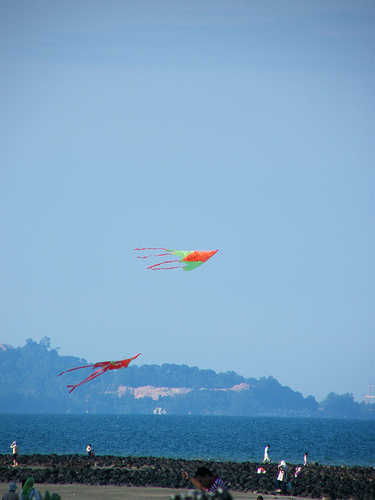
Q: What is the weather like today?
A: It is clear.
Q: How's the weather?
A: It is clear.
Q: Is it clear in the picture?
A: Yes, it is clear.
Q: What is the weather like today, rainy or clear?
A: It is clear.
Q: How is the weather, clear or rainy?
A: It is clear.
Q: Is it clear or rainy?
A: It is clear.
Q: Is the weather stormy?
A: No, it is clear.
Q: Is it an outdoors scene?
A: Yes, it is outdoors.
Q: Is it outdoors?
A: Yes, it is outdoors.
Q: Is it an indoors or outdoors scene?
A: It is outdoors.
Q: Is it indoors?
A: No, it is outdoors.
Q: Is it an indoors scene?
A: No, it is outdoors.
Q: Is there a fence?
A: No, there are no fences.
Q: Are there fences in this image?
A: No, there are no fences.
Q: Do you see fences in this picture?
A: No, there are no fences.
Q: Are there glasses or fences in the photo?
A: No, there are no fences or glasses.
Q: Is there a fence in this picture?
A: No, there are no fences.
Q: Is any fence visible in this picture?
A: No, there are no fences.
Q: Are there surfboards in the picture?
A: No, there are no surfboards.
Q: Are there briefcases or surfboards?
A: No, there are no surfboards or briefcases.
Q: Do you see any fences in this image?
A: No, there are no fences.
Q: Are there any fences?
A: No, there are no fences.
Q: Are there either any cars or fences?
A: No, there are no fences or cars.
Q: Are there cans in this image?
A: No, there are no cans.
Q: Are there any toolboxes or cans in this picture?
A: No, there are no cans or toolboxes.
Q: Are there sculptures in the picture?
A: No, there are no sculptures.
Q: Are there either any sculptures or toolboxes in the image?
A: No, there are no sculptures or toolboxes.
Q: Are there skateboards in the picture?
A: No, there are no skateboards.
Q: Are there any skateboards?
A: No, there are no skateboards.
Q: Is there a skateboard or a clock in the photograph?
A: No, there are no skateboards or clocks.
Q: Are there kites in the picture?
A: Yes, there is a kite.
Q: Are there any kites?
A: Yes, there is a kite.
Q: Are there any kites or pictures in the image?
A: Yes, there is a kite.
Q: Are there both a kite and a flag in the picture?
A: No, there is a kite but no flags.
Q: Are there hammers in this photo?
A: No, there are no hammers.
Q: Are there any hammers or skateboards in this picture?
A: No, there are no hammers or skateboards.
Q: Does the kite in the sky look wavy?
A: Yes, the kite is wavy.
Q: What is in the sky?
A: The kite is in the sky.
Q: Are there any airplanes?
A: No, there are no airplanes.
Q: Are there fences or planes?
A: No, there are no planes or fences.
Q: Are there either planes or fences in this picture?
A: No, there are no planes or fences.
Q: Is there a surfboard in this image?
A: No, there are no surfboards.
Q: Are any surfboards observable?
A: No, there are no surfboards.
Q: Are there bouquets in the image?
A: No, there are no bouquets.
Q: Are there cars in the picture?
A: No, there are no cars.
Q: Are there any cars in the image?
A: No, there are no cars.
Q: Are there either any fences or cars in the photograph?
A: No, there are no cars or fences.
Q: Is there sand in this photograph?
A: Yes, there is sand.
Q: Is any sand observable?
A: Yes, there is sand.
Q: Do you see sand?
A: Yes, there is sand.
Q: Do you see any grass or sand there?
A: Yes, there is sand.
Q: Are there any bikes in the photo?
A: No, there are no bikes.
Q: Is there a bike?
A: No, there are no bikes.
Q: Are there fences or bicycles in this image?
A: No, there are no bicycles or fences.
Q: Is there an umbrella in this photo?
A: No, there are no umbrellas.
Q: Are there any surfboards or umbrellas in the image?
A: No, there are no umbrellas or surfboards.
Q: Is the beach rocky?
A: Yes, the beach is rocky.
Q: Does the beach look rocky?
A: Yes, the beach is rocky.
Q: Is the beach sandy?
A: No, the beach is rocky.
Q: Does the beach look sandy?
A: No, the beach is rocky.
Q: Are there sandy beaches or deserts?
A: No, there is a beach but it is rocky.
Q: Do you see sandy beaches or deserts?
A: No, there is a beach but it is rocky.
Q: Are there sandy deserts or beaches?
A: No, there is a beach but it is rocky.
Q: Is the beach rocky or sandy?
A: The beach is rocky.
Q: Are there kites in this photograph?
A: Yes, there is a kite.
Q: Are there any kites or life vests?
A: Yes, there is a kite.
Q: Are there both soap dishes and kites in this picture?
A: No, there is a kite but no soap dishes.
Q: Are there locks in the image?
A: No, there are no locks.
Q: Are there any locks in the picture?
A: No, there are no locks.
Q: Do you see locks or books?
A: No, there are no locks or books.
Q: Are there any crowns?
A: No, there are no crowns.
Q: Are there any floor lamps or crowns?
A: No, there are no crowns or floor lamps.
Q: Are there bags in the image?
A: No, there are no bags.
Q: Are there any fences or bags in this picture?
A: No, there are no bags or fences.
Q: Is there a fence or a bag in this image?
A: No, there are no bags or fences.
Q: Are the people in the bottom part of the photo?
A: Yes, the people are in the bottom of the image.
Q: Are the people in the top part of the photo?
A: No, the people are in the bottom of the image.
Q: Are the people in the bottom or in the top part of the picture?
A: The people are in the bottom of the image.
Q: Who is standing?
A: The people are standing.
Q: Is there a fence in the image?
A: No, there are no fences.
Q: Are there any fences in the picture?
A: No, there are no fences.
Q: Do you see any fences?
A: No, there are no fences.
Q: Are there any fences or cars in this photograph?
A: No, there are no fences or cars.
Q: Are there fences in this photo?
A: No, there are no fences.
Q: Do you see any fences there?
A: No, there are no fences.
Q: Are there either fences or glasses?
A: No, there are no fences or glasses.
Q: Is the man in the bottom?
A: Yes, the man is in the bottom of the image.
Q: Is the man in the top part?
A: No, the man is in the bottom of the image.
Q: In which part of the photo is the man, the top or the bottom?
A: The man is in the bottom of the image.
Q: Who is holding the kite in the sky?
A: The man is holding the kite.